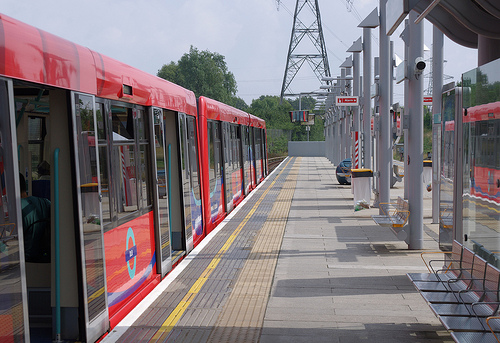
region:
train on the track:
[5, 28, 263, 320]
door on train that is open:
[11, 88, 76, 314]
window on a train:
[186, 118, 199, 177]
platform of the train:
[238, 197, 374, 342]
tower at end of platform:
[264, 6, 345, 118]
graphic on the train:
[99, 232, 150, 285]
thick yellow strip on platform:
[153, 315, 188, 335]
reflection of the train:
[441, 99, 499, 215]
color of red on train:
[106, 243, 125, 284]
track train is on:
[268, 148, 285, 161]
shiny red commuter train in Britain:
[3, 11, 271, 334]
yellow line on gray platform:
[150, 154, 295, 340]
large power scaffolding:
[276, 0, 335, 98]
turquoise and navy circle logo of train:
[116, 223, 146, 277]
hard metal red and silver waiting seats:
[405, 237, 498, 337]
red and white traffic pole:
[345, 128, 361, 178]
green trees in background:
[157, 42, 432, 179]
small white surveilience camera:
[409, 54, 425, 77]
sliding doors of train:
[152, 98, 203, 279]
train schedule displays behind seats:
[428, 58, 498, 269]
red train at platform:
[10, 34, 225, 336]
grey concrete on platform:
[280, 181, 370, 341]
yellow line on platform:
[150, 158, 275, 340]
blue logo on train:
[98, 207, 163, 285]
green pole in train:
[28, 154, 68, 338]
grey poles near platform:
[370, 45, 425, 252]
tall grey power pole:
[265, 0, 343, 121]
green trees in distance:
[140, 54, 355, 146]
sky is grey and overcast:
[201, 0, 282, 65]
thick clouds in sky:
[94, 8, 284, 58]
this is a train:
[6, 15, 278, 336]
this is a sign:
[12, 78, 105, 342]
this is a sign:
[152, 105, 200, 268]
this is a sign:
[215, 118, 242, 233]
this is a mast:
[264, 5, 324, 105]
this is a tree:
[151, 42, 242, 112]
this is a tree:
[250, 68, 312, 200]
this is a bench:
[431, 240, 497, 330]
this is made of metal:
[394, 28, 441, 256]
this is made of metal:
[354, 19, 379, 203]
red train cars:
[17, 52, 274, 267]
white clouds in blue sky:
[111, 13, 139, 54]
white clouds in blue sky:
[235, 13, 283, 67]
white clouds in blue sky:
[272, 19, 317, 66]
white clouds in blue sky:
[238, 26, 278, 87]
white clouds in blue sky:
[208, 11, 238, 45]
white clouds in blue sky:
[170, 1, 207, 52]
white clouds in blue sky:
[107, 23, 135, 43]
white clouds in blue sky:
[92, 5, 129, 37]